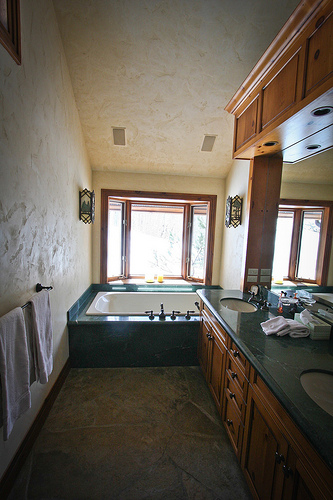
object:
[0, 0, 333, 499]
bathroom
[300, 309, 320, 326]
towel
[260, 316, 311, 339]
towel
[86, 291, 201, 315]
bath tub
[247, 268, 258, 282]
electrical outlet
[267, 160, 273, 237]
wall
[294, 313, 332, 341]
box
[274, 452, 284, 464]
knobs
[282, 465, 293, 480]
knobs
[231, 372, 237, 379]
knobs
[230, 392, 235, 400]
knobs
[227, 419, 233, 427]
knobs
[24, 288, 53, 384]
towel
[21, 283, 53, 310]
rod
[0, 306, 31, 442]
towel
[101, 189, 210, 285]
window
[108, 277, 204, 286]
sill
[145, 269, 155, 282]
candle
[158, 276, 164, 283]
candle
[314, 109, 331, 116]
vent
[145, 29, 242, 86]
ceiling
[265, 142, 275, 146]
vent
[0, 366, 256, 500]
floor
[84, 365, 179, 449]
part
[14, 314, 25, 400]
part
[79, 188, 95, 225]
light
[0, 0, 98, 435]
wall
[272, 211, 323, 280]
mirror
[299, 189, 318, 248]
part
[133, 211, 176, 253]
part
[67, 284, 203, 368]
marble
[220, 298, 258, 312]
sink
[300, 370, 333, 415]
sink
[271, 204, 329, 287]
window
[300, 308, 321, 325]
facial tissues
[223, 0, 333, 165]
cabinetry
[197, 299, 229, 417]
cabinetry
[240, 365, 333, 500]
cabinetry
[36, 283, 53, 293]
fixture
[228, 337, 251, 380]
drawer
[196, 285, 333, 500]
center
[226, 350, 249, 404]
drawer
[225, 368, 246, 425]
drawer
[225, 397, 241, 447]
drawer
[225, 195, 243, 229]
light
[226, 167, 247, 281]
wall